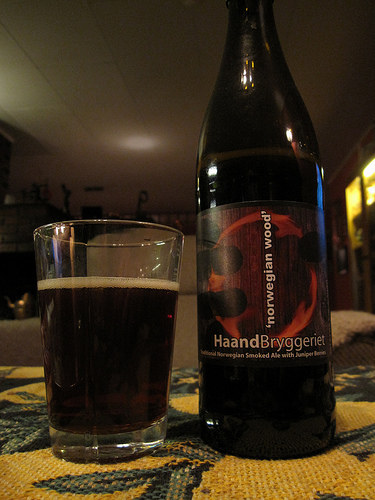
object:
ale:
[37, 274, 180, 435]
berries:
[191, 148, 336, 456]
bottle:
[194, 2, 339, 462]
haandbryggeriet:
[209, 332, 328, 353]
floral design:
[0, 364, 375, 499]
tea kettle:
[3, 288, 40, 322]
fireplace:
[0, 189, 67, 304]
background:
[0, 0, 371, 500]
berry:
[197, 283, 248, 322]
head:
[35, 272, 179, 291]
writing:
[205, 332, 329, 353]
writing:
[257, 209, 281, 328]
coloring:
[23, 462, 216, 497]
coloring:
[204, 205, 323, 342]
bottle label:
[199, 200, 331, 360]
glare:
[201, 413, 221, 431]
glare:
[47, 222, 73, 237]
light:
[116, 132, 161, 151]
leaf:
[24, 469, 152, 491]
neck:
[221, 1, 291, 71]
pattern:
[0, 382, 248, 498]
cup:
[31, 216, 183, 463]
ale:
[194, 2, 335, 458]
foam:
[35, 274, 180, 293]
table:
[0, 364, 375, 500]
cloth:
[0, 366, 375, 496]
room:
[2, 5, 375, 500]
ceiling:
[1, 4, 375, 220]